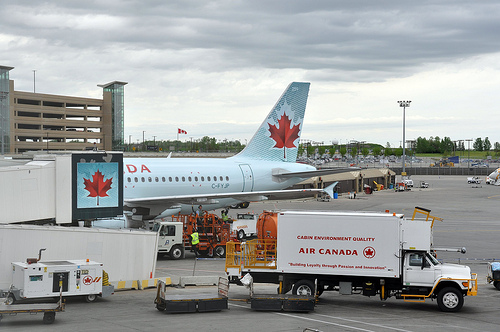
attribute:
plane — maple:
[54, 65, 357, 230]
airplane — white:
[31, 78, 335, 225]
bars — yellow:
[378, 270, 476, 304]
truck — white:
[221, 211, 476, 312]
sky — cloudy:
[7, 5, 496, 81]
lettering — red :
[286, 232, 386, 270]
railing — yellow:
[218, 234, 282, 271]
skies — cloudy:
[0, 0, 500, 150]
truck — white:
[270, 206, 478, 314]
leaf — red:
[265, 104, 300, 153]